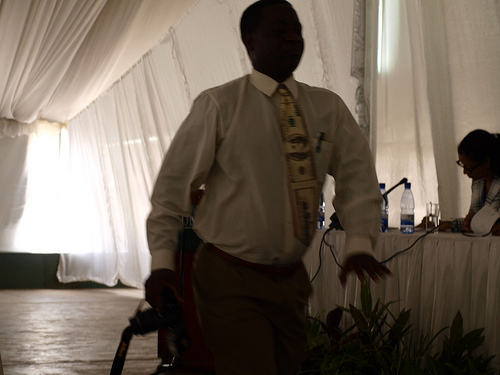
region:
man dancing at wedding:
[131, 9, 386, 367]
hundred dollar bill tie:
[248, 79, 326, 244]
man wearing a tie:
[165, 13, 368, 373]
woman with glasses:
[420, 106, 498, 259]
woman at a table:
[428, 127, 498, 244]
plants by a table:
[303, 277, 465, 367]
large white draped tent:
[35, 26, 480, 313]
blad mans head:
[239, 0, 315, 90]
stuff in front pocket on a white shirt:
[302, 121, 337, 162]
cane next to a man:
[105, 277, 190, 373]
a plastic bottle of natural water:
[399, 180, 415, 233]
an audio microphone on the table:
[382, 173, 408, 198]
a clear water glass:
[425, 199, 440, 231]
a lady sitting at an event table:
[439, 129, 499, 236]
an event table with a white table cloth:
[311, 230, 499, 345]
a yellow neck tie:
[274, 79, 319, 248]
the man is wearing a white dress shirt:
[145, 69, 383, 266]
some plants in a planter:
[313, 290, 499, 373]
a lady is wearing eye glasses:
[456, 154, 466, 168]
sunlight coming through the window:
[1, 115, 133, 287]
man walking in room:
[130, 0, 403, 355]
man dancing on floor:
[125, 15, 432, 365]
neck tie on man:
[268, 90, 325, 238]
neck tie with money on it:
[271, 92, 323, 248]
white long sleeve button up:
[138, 83, 430, 315]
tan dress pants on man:
[186, 244, 331, 367]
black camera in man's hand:
[119, 288, 184, 343]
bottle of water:
[397, 176, 417, 233]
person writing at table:
[446, 135, 498, 250]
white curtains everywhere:
[0, 0, 181, 245]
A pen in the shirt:
[314, 129, 325, 154]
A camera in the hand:
[126, 288, 188, 339]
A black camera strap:
[107, 336, 132, 374]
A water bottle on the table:
[399, 180, 417, 234]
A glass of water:
[424, 200, 441, 236]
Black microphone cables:
[319, 230, 334, 257]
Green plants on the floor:
[330, 320, 420, 374]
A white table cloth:
[424, 243, 499, 315]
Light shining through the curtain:
[379, 1, 399, 77]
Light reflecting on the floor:
[24, 291, 66, 373]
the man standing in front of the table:
[148, 2, 397, 367]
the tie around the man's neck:
[269, 87, 316, 251]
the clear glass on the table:
[425, 200, 441, 234]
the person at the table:
[428, 124, 499, 234]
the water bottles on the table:
[378, 180, 417, 234]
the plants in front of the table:
[311, 275, 496, 373]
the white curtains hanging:
[60, 2, 499, 284]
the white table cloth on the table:
[305, 223, 499, 348]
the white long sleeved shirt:
[148, 69, 381, 270]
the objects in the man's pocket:
[313, 128, 329, 155]